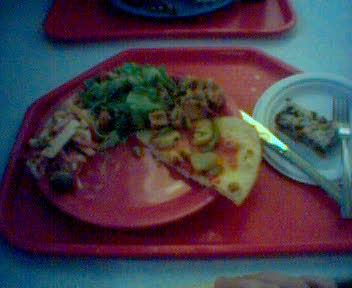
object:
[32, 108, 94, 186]
toppings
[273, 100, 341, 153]
dessert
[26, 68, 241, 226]
plate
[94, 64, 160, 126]
food items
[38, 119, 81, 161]
food items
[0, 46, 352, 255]
tray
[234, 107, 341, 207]
knief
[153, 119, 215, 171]
decoration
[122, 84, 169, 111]
leaves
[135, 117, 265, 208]
food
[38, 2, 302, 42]
lunch tray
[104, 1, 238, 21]
plate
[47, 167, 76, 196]
food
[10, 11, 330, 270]
table